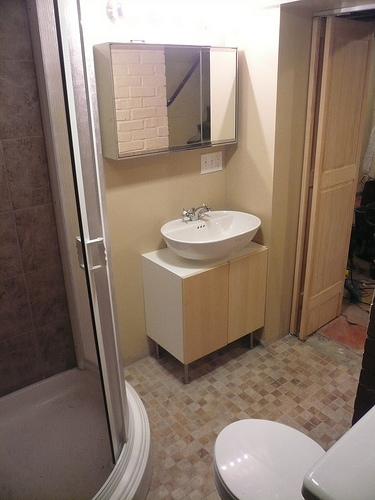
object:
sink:
[158, 205, 260, 266]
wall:
[79, 0, 227, 372]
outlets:
[199, 151, 223, 175]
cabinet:
[140, 247, 228, 366]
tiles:
[25, 268, 69, 331]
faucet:
[183, 200, 211, 223]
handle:
[181, 202, 195, 219]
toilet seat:
[212, 417, 325, 499]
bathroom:
[0, 0, 375, 499]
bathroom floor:
[124, 332, 363, 498]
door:
[1, 1, 125, 499]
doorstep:
[307, 332, 362, 370]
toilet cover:
[213, 416, 324, 499]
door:
[298, 14, 372, 342]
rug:
[318, 300, 371, 355]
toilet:
[214, 402, 375, 498]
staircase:
[187, 105, 212, 145]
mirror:
[164, 45, 210, 149]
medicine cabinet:
[92, 41, 238, 159]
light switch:
[199, 151, 222, 172]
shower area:
[2, 0, 155, 499]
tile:
[181, 394, 193, 404]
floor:
[120, 274, 375, 498]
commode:
[212, 402, 375, 498]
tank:
[300, 402, 375, 498]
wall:
[0, 0, 76, 396]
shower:
[0, 0, 150, 499]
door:
[183, 266, 229, 365]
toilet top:
[213, 417, 326, 498]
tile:
[169, 420, 181, 430]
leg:
[183, 361, 189, 382]